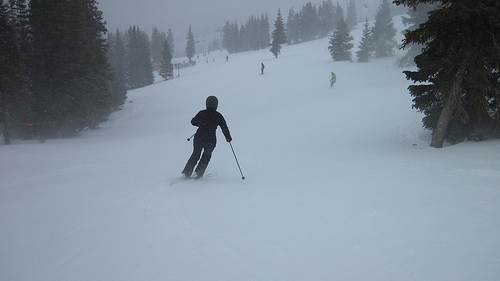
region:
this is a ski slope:
[35, 40, 444, 230]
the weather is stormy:
[65, 8, 435, 244]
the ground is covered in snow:
[41, 188, 193, 268]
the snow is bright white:
[46, 168, 155, 267]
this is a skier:
[162, 89, 279, 175]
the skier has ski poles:
[172, 100, 264, 215]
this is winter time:
[23, 34, 443, 190]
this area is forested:
[25, 22, 145, 107]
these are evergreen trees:
[27, 30, 142, 205]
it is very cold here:
[68, 34, 480, 239]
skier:
[168, 79, 246, 176]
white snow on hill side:
[307, 201, 347, 232]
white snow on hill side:
[370, 236, 405, 264]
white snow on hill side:
[355, 201, 426, 235]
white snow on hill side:
[264, 185, 318, 246]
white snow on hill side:
[171, 193, 213, 227]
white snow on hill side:
[180, 235, 260, 279]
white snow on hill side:
[45, 178, 93, 210]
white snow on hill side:
[97, 209, 162, 254]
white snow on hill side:
[291, 81, 318, 118]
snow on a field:
[17, 213, 84, 253]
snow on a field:
[119, 230, 174, 270]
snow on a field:
[238, 208, 317, 267]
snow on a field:
[375, 218, 413, 258]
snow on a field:
[362, 153, 392, 180]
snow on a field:
[301, 127, 333, 152]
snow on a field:
[271, 93, 298, 112]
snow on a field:
[198, 58, 223, 80]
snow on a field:
[160, 96, 179, 109]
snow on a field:
[432, 223, 467, 258]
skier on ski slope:
[172, 86, 249, 181]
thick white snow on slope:
[190, 134, 397, 268]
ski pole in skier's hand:
[221, 129, 248, 190]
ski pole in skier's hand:
[184, 109, 194, 146]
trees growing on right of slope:
[421, 21, 498, 158]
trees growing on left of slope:
[2, 10, 110, 132]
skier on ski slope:
[317, 67, 345, 89]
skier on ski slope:
[253, 62, 273, 79]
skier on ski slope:
[224, 52, 251, 69]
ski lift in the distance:
[188, 10, 234, 45]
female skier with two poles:
[163, 83, 255, 199]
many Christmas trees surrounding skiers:
[2, 3, 497, 182]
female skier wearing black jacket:
[165, 87, 257, 198]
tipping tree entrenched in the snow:
[379, 0, 499, 170]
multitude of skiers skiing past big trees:
[172, 23, 272, 70]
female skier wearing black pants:
[171, 92, 254, 196]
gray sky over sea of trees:
[8, 0, 446, 90]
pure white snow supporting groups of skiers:
[124, 40, 397, 277]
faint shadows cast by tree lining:
[4, 6, 166, 166]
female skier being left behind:
[163, 23, 356, 202]